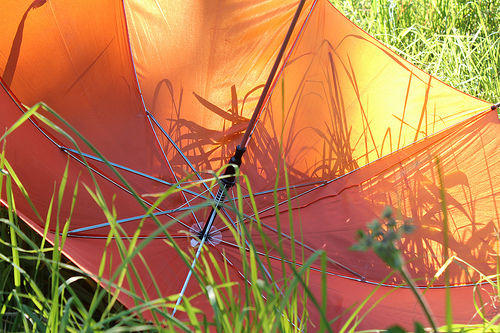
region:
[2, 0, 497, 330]
Umbrella is bright orange.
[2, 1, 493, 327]
Umbrella is completely open.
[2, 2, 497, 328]
Umbrella is upside down.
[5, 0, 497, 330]
Umbrella laying on grass.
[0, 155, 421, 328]
Grass needs to be mowed.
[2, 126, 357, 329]
Grass is tall and green.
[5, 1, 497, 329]
Spokes on umbrella are metal.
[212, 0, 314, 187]
Umbrella has a handle.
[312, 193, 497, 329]
Wildflower grows amid the grass.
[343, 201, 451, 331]
Wildflower had buds on it.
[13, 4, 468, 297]
Light orange umbrella in grassy area.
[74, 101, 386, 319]
Metal silver wires that line the inside of umbrella.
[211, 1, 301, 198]
Black stem of inside of umbrella.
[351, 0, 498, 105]
Small patch of grass.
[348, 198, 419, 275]
Small flower beside umbrella.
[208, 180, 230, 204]
Small spring on umbrella.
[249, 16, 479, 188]
Shadow of grass blades on umbrella.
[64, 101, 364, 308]
Star shaped metal bars in umbrella.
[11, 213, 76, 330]
Small patch of grass.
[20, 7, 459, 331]
Orange umbrella laying in grass.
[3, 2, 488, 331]
the umbrella is orange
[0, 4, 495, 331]
the grass is green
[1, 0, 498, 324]
the grass is long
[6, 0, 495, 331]
the umbrella is upside down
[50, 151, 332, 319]
the umbrella has metal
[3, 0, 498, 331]
the umbrella fell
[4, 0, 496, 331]
the umbrella is on the ground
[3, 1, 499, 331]
the umbrella has fabric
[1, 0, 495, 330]
the grass casts shadows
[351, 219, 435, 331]
the plant is in the foreground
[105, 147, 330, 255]
the frame is mettallic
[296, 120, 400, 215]
shadow of grass on the umbrella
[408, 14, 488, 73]
the grass is green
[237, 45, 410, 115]
sunlight refection on the umbrella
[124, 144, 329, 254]
the frame is silver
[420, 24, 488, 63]
sun refection on the grass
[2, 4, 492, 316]
its a daytime photo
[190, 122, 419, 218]
shadow of grass on the umbrella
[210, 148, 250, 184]
the object is black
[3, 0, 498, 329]
the umbrella is abandoned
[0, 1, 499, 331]
the umbrella is open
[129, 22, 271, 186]
there is a shadow from the grass on the umbrella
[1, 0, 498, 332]
tall grass surrounds the umbrella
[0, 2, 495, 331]
the umbrella is in a grassy field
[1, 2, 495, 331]
the umbrella is orangey red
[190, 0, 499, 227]
a shadow covered panel on the umbrells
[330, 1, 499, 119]
there is grass behind the umbrella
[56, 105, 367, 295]
the umbrella has metal spokes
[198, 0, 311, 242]
the umbrella has a handle